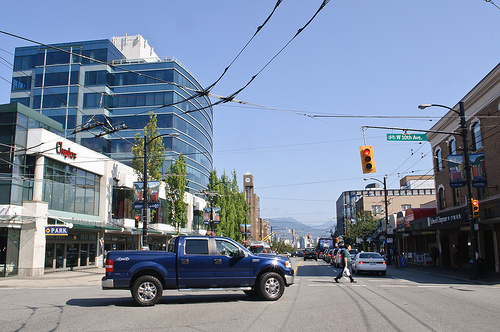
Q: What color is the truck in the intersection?
A: Blue.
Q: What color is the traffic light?
A: Red.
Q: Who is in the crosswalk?
A: A man carrying groceries.